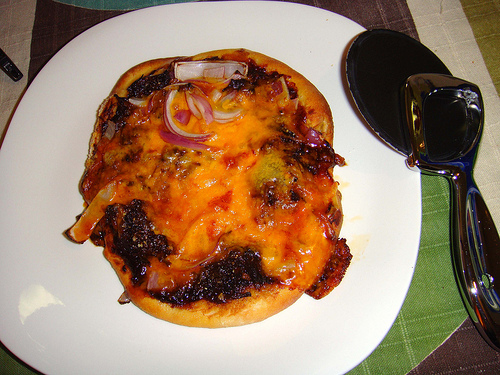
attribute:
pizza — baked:
[60, 44, 355, 330]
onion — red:
[162, 97, 202, 139]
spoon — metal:
[341, 28, 498, 343]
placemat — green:
[412, 267, 465, 362]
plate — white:
[44, 289, 118, 370]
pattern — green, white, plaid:
[422, 175, 499, 292]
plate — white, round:
[3, 0, 423, 374]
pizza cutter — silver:
[66, 46, 353, 328]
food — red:
[75, 47, 382, 327]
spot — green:
[247, 148, 294, 199]